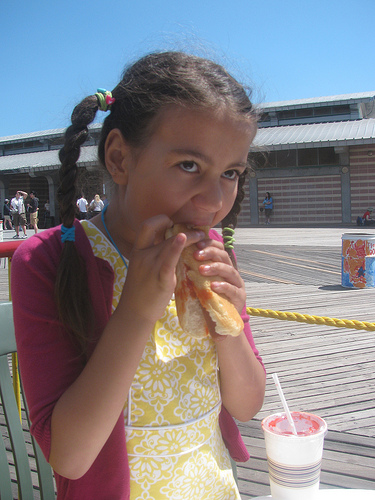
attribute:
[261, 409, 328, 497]
drink — red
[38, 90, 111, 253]
pigtail — brown 